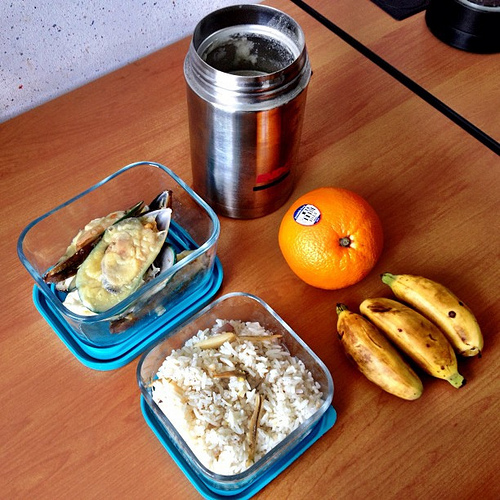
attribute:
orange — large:
[276, 185, 384, 294]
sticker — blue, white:
[289, 201, 325, 228]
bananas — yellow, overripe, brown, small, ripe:
[332, 270, 486, 405]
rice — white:
[144, 315, 324, 477]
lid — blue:
[30, 208, 225, 372]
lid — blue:
[138, 369, 339, 500]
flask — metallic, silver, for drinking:
[180, 3, 316, 224]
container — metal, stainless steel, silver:
[181, 2, 309, 220]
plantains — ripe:
[333, 269, 488, 401]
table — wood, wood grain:
[1, 1, 498, 500]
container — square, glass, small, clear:
[140, 288, 337, 490]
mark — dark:
[365, 301, 393, 313]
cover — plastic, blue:
[30, 219, 225, 372]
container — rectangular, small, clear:
[17, 159, 223, 347]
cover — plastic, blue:
[139, 370, 340, 499]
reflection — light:
[208, 70, 242, 221]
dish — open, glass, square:
[134, 290, 337, 498]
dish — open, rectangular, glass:
[13, 159, 223, 351]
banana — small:
[379, 270, 485, 358]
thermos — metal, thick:
[180, 2, 316, 221]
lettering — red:
[252, 149, 295, 183]